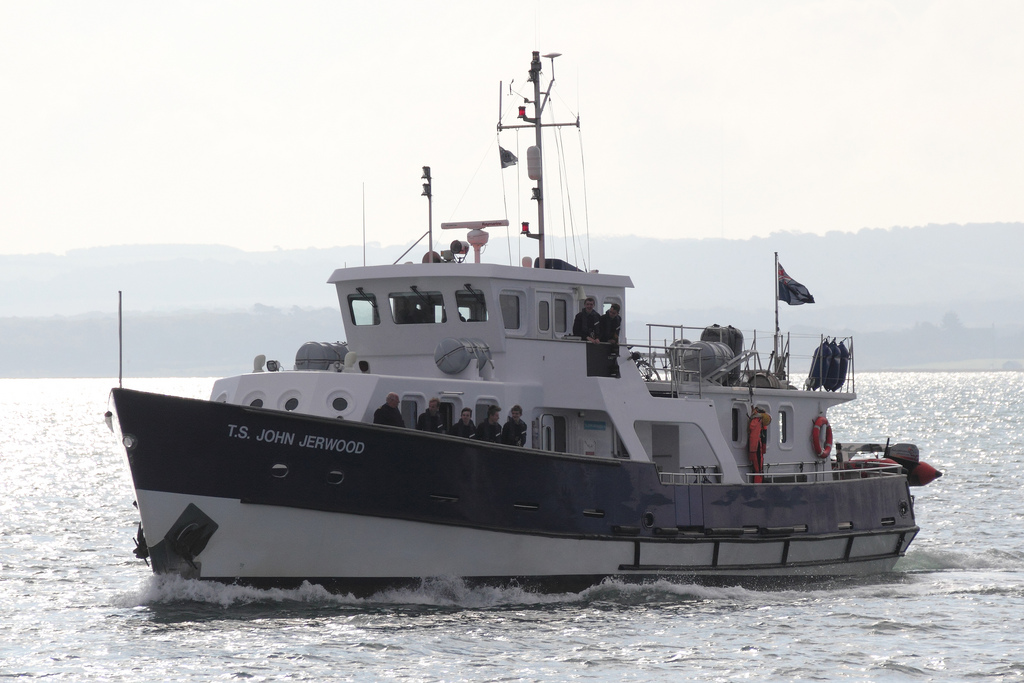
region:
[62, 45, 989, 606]
boat on the water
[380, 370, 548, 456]
a row of people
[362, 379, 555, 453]
people standing on the boat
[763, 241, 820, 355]
flag on a pole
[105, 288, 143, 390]
narrow pole on the front of the boat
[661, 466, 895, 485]
white railing around the boat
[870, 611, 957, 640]
ripple in the water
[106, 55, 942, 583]
a small ship on water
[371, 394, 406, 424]
a man standing on the deck of a ship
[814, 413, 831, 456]
a life preserver ring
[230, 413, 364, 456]
he name of a ship on the ship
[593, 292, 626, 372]
a man in black on the deck of a ship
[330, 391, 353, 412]
a small round window on a ship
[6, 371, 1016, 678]
a large body of water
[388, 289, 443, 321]
a window on the front of a ship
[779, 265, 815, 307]
a flag on a ship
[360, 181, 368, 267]
an antenna on a ship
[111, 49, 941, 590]
A luxuryb yacht in the water body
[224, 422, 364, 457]
The name of the yacht painted on its side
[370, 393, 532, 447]
Some passengers on the deck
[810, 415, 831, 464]
A safety float hung on the cabin wall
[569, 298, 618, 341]
Two persons on the upper deck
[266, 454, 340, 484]
Two of the portholes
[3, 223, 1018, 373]
Hills with vegetation on the faraway shore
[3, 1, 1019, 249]
Bright morning sky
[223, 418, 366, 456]
Lettering on the boat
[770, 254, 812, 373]
A flag on a pole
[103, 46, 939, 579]
A large boat on the water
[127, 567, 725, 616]
Water splashing up around the boat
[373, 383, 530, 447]
Men leaning over the side of the boat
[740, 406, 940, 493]
Orange equipment on the boat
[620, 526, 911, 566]
A railing on the boat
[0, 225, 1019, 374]
Land and mountains behind the boat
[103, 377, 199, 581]
The pointed front of the boat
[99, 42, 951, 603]
black and white cabin cruiser at sea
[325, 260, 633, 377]
boat cockpit has three front windows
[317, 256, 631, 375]
two people standing on upper level of boat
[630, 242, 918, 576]
flag on rear upper deck of boat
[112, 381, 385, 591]
name of boat in white letters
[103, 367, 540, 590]
four portholes in front cabin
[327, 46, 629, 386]
several antennas on roof of boat's cockpit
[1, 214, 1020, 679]
the shoreline is hilly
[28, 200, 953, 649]
boat in the water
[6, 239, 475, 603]
front of the boat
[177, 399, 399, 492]
words on the boat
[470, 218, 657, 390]
windows on the boat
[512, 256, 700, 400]
people on the boat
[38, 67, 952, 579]
black and white boat in water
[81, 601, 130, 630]
ripples in dark gray water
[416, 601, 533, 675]
ripples in dark gray water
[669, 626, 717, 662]
ripples in dark gray water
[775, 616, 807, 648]
ripples in dark gray water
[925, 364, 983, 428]
ripples in dark gray water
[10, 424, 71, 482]
ripples in dark gray water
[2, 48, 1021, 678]
the boat is on the water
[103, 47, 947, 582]
the letters on the boat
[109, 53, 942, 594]
the people on the boat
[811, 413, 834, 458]
the lifesaver is orange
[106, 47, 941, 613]
the boat is white and dark blue